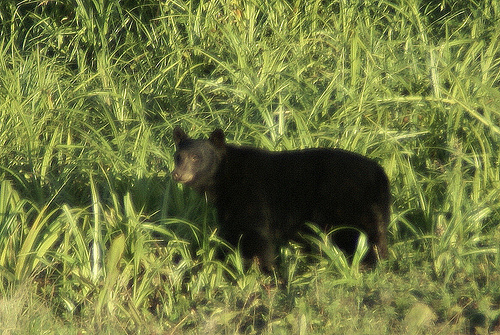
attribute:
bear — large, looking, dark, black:
[169, 125, 396, 275]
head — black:
[168, 122, 227, 186]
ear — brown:
[208, 128, 226, 143]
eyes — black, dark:
[174, 152, 200, 164]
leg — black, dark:
[252, 235, 284, 273]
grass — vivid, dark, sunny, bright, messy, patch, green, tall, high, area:
[1, 2, 499, 334]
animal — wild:
[167, 122, 398, 289]